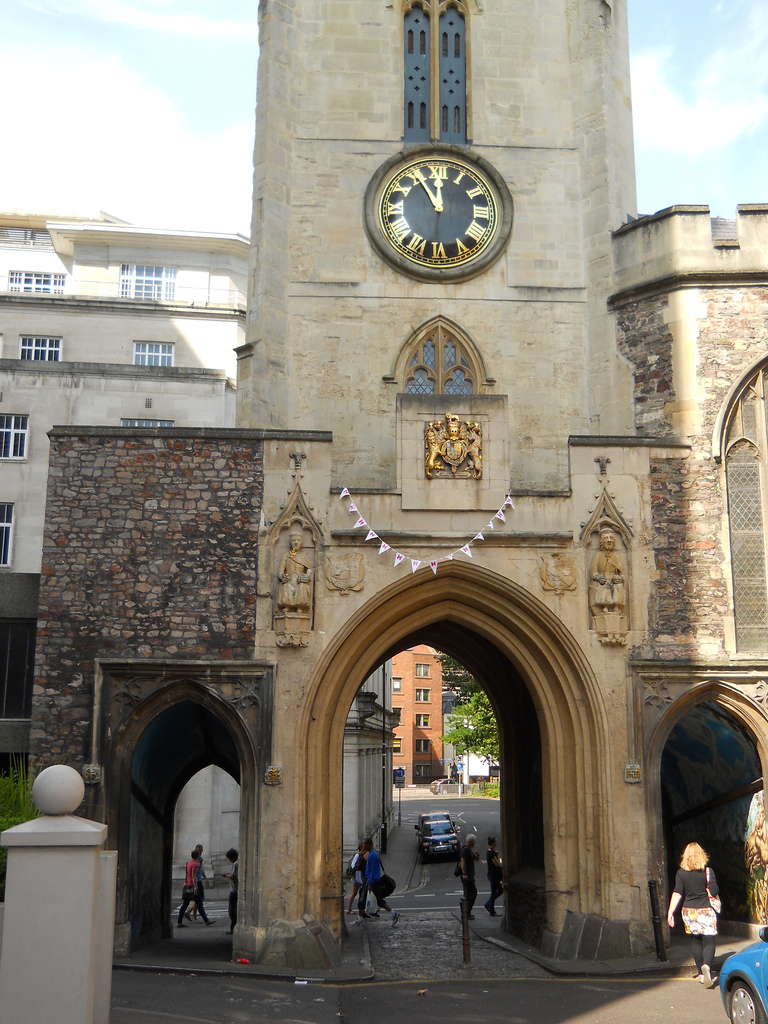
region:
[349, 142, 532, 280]
A large round clock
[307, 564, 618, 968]
A tall arched doorway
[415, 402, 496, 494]
A gold design above doorway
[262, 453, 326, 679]
A carved design on left of arch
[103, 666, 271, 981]
A smaller arched doorway on left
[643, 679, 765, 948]
A smaller arch on right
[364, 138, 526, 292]
Gold roman numerals on clock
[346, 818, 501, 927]
People walking on street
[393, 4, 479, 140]
Window above clock at top of the building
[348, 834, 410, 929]
a man carrying a black gym bag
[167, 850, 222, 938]
a woman wearing tight skinny jeans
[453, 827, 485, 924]
an elderly man wearing a dark shirt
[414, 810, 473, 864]
a pair of cars parked on the street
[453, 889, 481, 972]
a small metal post in the road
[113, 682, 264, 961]
a covered walkway with an arched entry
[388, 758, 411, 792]
a pair of traffic signs on a post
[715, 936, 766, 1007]
the hood of a bright blue car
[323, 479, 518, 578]
a banner of flags hanging over an arch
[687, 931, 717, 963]
woman wearing black tights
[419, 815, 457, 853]
car parked on the street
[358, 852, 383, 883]
man wearing a blue shirt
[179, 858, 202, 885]
woman wearing a pink shirt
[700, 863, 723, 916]
woman holding a purse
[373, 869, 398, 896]
woman holding a black purse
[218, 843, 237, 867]
woman with black hair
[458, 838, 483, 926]
the person is standing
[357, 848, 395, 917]
the person is standing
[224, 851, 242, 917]
the person is standing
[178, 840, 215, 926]
the person is standing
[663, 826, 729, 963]
the person is standing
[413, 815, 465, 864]
car on the road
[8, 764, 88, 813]
cricle on the pole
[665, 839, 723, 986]
lady is walking into archway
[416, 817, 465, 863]
car is parked beside side walk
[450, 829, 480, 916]
man is walking beside street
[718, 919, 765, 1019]
car is in front of building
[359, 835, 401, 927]
man is holding a bag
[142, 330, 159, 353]
a window on the building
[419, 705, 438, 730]
a window on the building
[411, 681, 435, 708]
a window on the building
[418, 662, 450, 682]
a window on the building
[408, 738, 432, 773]
a window on the building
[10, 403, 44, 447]
a window on the building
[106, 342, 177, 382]
a window on the building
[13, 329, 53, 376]
a window on the building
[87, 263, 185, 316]
a window on the building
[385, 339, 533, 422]
a window on the building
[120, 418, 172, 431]
A window on a building.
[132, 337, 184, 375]
A window on a building.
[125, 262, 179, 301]
A window on a building.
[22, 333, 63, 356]
A window on a building.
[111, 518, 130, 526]
A stone in a wall.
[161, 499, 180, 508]
A stone in a wall.